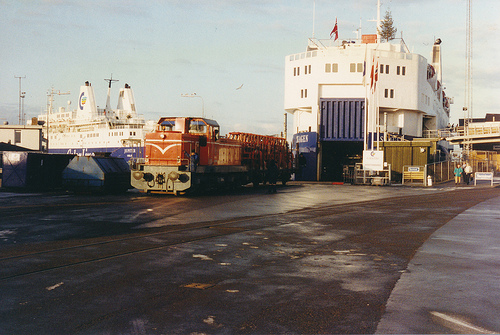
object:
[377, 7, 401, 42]
tree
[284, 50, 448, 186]
building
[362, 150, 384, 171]
sign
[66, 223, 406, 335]
line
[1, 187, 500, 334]
road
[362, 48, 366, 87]
flags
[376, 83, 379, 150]
poles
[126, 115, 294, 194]
train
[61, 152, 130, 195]
dumpsters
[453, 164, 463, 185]
people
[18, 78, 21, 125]
pole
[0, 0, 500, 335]
background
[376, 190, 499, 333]
street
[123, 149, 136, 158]
name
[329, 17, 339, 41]
flag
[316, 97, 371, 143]
door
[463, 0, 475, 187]
tower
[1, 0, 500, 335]
harbor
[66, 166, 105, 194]
shadows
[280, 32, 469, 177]
ships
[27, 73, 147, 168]
boat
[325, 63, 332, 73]
windows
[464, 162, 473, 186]
man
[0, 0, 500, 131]
sky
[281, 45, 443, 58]
roof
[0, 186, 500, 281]
tracks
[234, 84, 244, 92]
birds